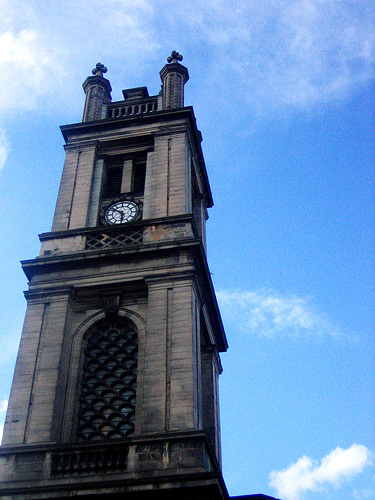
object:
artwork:
[90, 62, 108, 78]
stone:
[169, 364, 192, 372]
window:
[77, 317, 143, 445]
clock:
[100, 196, 143, 227]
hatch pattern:
[84, 228, 143, 252]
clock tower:
[0, 49, 229, 498]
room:
[104, 167, 145, 194]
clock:
[101, 196, 139, 224]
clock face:
[106, 200, 138, 224]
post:
[160, 50, 190, 110]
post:
[81, 63, 112, 118]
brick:
[173, 304, 190, 308]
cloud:
[0, 0, 375, 499]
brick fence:
[107, 94, 158, 116]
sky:
[2, 1, 372, 497]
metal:
[83, 227, 143, 250]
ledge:
[20, 212, 200, 267]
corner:
[174, 105, 198, 135]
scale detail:
[78, 321, 139, 441]